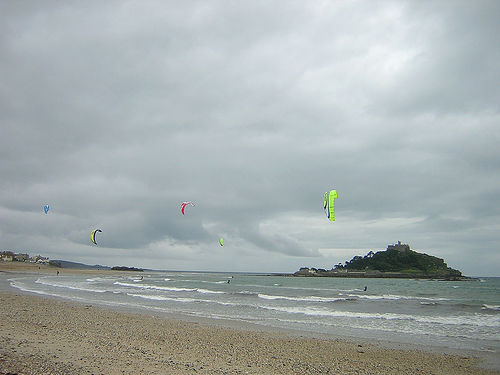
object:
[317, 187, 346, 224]
kite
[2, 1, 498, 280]
sky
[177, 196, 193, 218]
kite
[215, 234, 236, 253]
kite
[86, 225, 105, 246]
kite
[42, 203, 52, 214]
kite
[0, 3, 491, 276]
clouds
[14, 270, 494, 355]
waves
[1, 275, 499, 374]
beach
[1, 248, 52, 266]
buildings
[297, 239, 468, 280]
mountains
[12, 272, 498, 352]
water